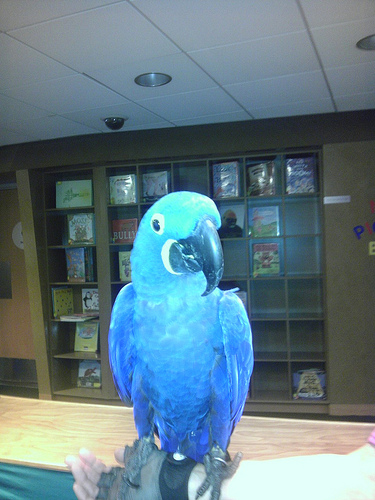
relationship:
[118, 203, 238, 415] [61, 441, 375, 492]
parrot on arm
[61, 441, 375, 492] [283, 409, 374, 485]
arm of man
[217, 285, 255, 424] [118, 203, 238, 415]
wing of parrot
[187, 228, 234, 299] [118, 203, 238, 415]
beak of parrot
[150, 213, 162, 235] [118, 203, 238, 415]
eye of parrot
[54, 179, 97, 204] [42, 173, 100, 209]
book in hole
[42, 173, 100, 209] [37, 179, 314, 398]
hole of cubby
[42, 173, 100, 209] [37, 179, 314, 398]
hole in cubby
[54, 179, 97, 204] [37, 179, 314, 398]
book in cubby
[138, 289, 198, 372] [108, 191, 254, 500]
feathers of parrot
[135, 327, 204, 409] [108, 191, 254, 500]
belly of parrot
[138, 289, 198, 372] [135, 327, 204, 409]
feathers of belly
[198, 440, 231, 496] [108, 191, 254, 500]
foot of parrot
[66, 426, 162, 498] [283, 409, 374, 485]
hand of man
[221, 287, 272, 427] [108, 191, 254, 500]
wing of parrot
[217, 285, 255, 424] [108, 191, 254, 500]
wing of parrot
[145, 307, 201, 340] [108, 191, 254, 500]
chest of parrot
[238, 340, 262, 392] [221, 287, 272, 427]
feathers of wing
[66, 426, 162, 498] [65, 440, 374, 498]
hand of man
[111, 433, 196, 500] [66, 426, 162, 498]
glove on hand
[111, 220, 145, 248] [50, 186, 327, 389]
book on shelf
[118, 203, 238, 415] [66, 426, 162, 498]
parrot on hand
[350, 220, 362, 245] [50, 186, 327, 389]
p on shelf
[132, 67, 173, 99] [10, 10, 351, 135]
light on ceiling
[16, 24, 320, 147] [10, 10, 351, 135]
tile on ceiling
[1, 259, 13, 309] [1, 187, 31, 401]
handle on door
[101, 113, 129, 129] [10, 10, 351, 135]
camera on ceiling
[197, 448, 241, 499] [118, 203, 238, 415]
talon of parrot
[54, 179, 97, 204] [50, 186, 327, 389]
book on shelf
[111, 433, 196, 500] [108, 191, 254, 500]
glove for parrot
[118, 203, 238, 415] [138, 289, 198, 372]
parrot with feathers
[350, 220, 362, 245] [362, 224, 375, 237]
p and i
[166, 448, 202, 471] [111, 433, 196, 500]
buckle on glove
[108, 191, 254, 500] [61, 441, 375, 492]
parrot on arm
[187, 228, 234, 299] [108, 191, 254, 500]
beak of parrot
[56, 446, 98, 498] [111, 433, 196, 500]
fingers in glove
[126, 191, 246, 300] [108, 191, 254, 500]
head of parrot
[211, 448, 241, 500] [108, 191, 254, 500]
talon of parrot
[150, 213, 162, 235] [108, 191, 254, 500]
eye of parrot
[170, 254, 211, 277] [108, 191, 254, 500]
mouth of parrot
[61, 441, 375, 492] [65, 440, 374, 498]
arm of man